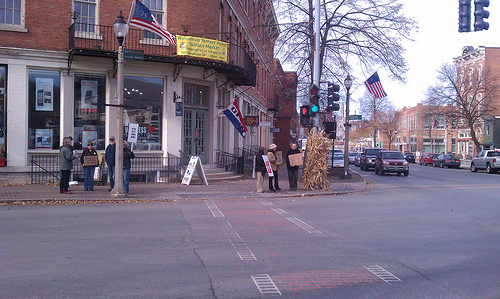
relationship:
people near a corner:
[61, 135, 138, 195] [215, 130, 367, 205]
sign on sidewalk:
[180, 154, 211, 189] [6, 177, 281, 199]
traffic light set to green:
[312, 81, 342, 114] [311, 106, 320, 113]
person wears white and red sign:
[249, 149, 273, 195] [262, 156, 274, 176]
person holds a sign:
[285, 139, 305, 192] [288, 153, 303, 167]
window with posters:
[28, 67, 63, 149] [37, 78, 54, 148]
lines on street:
[205, 187, 405, 293] [3, 174, 499, 298]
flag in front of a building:
[131, 2, 173, 43] [1, 1, 280, 180]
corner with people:
[215, 130, 367, 205] [61, 135, 138, 195]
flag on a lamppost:
[365, 72, 386, 100] [346, 74, 352, 176]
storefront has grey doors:
[1, 49, 264, 187] [183, 107, 209, 166]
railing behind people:
[33, 148, 183, 183] [61, 135, 138, 195]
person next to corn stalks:
[285, 139, 305, 192] [300, 126, 329, 194]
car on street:
[374, 148, 407, 177] [344, 149, 500, 192]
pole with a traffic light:
[314, 5, 321, 87] [312, 81, 342, 114]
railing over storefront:
[66, 23, 257, 92] [1, 49, 264, 187]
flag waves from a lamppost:
[131, 2, 173, 43] [118, 47, 127, 171]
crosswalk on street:
[220, 197, 384, 298] [3, 174, 499, 298]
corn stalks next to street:
[300, 126, 329, 194] [3, 174, 499, 298]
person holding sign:
[285, 139, 305, 192] [287, 150, 307, 170]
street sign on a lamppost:
[350, 115, 362, 122] [346, 74, 352, 176]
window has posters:
[28, 67, 63, 149] [37, 78, 54, 148]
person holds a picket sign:
[124, 140, 135, 192] [129, 120, 140, 147]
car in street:
[472, 149, 499, 174] [344, 149, 500, 192]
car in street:
[374, 148, 407, 177] [344, 149, 500, 192]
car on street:
[434, 149, 463, 170] [344, 149, 500, 192]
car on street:
[472, 149, 499, 174] [344, 149, 500, 192]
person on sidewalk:
[249, 149, 273, 195] [6, 177, 281, 199]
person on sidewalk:
[285, 139, 305, 192] [6, 177, 281, 199]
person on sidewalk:
[124, 140, 135, 192] [6, 177, 281, 199]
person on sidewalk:
[56, 131, 76, 192] [6, 177, 281, 199]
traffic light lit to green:
[312, 81, 342, 114] [311, 106, 320, 113]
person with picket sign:
[124, 140, 135, 192] [129, 120, 140, 147]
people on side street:
[255, 136, 303, 190] [344, 149, 500, 192]